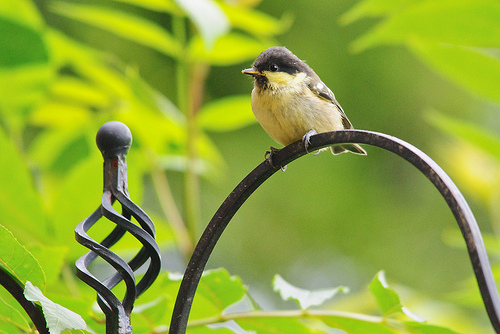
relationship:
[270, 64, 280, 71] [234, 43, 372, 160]
black eye of bird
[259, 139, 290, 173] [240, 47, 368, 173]
foot belonging to bird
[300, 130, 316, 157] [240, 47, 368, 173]
bird feet belonging to bird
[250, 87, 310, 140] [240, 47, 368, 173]
belly belonging to bird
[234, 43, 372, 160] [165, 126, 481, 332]
bird perched on wire structure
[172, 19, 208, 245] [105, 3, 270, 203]
stock belonging to plant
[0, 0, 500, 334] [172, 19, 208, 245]
leaf growing on stock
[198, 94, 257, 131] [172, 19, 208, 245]
leaf growing on stock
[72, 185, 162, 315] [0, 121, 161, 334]
twist decorating iron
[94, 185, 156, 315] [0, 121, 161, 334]
twist decorating iron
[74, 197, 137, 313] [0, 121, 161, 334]
twist decorating iron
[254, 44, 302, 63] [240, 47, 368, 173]
bonnet belonging to bird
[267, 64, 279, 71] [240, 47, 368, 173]
black eye belonging to bird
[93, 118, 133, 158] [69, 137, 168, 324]
top decorating iron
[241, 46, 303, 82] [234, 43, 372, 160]
head belonging to bird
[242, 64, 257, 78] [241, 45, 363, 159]
beak belonging to bird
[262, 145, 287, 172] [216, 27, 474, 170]
foot belonging to bird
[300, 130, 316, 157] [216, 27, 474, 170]
bird feet belonging to bird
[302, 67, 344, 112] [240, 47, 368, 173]
wing belonging to bird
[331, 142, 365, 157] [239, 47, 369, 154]
tail belonging to bird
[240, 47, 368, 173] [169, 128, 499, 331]
bird sitting on metal